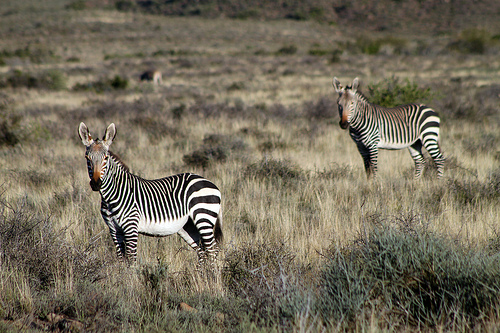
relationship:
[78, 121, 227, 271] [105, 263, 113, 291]
zebra standing on grass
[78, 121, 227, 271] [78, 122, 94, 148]
zebra has ear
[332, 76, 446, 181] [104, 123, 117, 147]
zebra has ear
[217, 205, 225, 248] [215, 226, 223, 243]
tail has hair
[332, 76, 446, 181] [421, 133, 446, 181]
zebra has leg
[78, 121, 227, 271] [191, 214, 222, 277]
zebra has leg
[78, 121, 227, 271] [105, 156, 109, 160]
zebra has eye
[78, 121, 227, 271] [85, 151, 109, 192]
zebra has face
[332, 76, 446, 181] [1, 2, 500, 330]
zebra standing in field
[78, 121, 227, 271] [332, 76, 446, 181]
zebra near zebra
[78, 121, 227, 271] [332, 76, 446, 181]
zebra stands near zebra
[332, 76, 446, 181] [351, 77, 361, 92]
zebra has ear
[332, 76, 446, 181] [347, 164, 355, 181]
zebra standing on grass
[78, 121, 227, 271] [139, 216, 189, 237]
zebra has belly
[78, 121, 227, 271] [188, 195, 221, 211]
zebra has stripe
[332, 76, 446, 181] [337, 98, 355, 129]
zebra has face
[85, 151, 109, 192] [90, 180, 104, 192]
face has nose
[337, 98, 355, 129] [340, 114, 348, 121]
face has brown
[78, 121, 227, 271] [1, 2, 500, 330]
zebra stands in field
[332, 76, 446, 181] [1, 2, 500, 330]
zebra stands in field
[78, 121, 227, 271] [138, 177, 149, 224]
zebra has stripe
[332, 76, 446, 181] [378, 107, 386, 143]
zebra has stripe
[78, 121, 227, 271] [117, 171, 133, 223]
zebra has stripe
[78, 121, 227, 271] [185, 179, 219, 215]
zebra has stripe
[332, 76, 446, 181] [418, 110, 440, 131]
zebra has stripe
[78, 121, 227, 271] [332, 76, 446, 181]
zebra standing near zebra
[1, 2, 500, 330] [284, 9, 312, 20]
field has shrub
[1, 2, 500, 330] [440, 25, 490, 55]
field has shrub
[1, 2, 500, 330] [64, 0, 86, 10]
field has shrub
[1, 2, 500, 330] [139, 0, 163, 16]
field has shrub